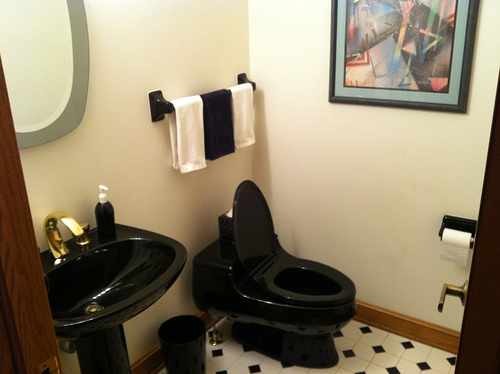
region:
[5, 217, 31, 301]
Brown door jamb on the left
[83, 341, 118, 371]
Black base of the sink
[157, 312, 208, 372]
Trash can between the sink and the toilet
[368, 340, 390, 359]
Black diamond in the tile on the floor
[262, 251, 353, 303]
Black toilet seat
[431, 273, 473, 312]
Gold handle on the structure in front of the toilet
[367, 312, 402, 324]
Light brown base between the wall and the floor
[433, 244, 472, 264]
Sheet of toilet paper that is hanging off the roll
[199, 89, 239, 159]
Black towel in the middle of the two white towels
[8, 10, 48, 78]
Face of the mirror above the sink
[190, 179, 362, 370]
toilet is black and shiny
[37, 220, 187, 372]
sink is black and shiny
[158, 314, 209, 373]
waste basket is black and shiny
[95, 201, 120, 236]
soap dispenser is black and shiny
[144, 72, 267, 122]
towel rack is black and shiny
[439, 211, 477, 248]
toilet paper dispenser is black and shiny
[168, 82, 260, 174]
towel rack has three towels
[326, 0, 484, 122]
artwork is abstract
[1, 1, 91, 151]
oval mirror on wall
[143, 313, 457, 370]
floor is checkered tile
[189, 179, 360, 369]
Black toilet with lid up.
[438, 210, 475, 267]
Toilet paper holder with a roll of toilet paper in it.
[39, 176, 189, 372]
Black pedestal sink.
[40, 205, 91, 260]
Shiny gold faucet.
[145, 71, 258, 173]
Towel rack holding three hand towels.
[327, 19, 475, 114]
Artwork in black frame.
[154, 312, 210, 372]
Black trash can.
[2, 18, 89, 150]
Mirror with silver frame.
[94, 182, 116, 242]
Black container of hand soap with white pump.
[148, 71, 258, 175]
Towel rack with two white towels and one black towel.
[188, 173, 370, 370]
A BLACK TOILET WITH A TISSUE BOX ON THE TANK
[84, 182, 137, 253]
BLACK SOAP PUMP DISPENSER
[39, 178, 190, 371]
BLACK SINK WITH A GOLD COLORED FAUCET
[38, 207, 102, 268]
GOLD COLORED FAUCET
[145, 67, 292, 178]
BLACK AND WHITE BATHROOM TOWELS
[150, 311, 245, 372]
A BLACK TRASH CAN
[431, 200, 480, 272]
TOILET PAPER HANGER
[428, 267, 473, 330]
BATHROOM DOOR HANDLE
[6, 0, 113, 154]
A MIRROR OVER THE SINK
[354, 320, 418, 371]
BLACK AND WHITE FLOOR TILES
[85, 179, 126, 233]
a soap container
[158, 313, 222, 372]
garbage can sitting on the floor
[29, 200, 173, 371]
a bathroom sink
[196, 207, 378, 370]
A black toilet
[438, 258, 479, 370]
The bathroom door handle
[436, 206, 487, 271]
toilet paper and the dispenser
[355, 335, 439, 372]
checkered pattern floor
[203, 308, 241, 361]
water pipe going to the toilet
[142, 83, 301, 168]
towel hanging on a rack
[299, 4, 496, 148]
picture hanging in the bathroom